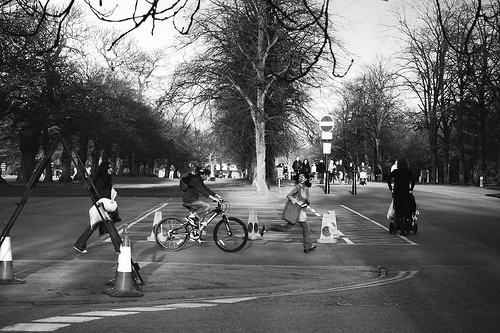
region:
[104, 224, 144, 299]
orange and white safety cone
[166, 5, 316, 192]
tree with no leaves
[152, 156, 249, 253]
boy riding a bicycle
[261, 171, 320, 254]
girl running across street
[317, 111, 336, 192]
round sign with white line through it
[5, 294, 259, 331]
white stripes painted on road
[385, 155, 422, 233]
woman pushing a baby carriage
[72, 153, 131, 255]
girl walking across street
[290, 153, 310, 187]
couple walking arm in arm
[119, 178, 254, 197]
shadow cast by tree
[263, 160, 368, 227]
Person runing acros the road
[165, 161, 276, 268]
man on a bicyvcle crossing the road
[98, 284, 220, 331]
road has white strip across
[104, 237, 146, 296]
black and white cones on th e road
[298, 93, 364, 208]
street light on th street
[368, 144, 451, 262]
man running through the highway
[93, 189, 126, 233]
lady carying a white sack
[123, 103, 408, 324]
the background color is black and white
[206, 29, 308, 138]
the tees in the middle of the road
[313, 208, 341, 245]
white cones on the road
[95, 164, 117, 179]
Person has long hair.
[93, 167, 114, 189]
Person has dark hair.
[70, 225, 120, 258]
Person wearing dark pants.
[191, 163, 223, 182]
Helmet on person's head.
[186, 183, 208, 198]
Person wearing dark shirt.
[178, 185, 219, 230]
Person riding on bike.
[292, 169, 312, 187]
Person has dark hair.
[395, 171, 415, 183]
Person wearing dark shirt.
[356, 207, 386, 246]
White lines marking road.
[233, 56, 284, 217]
Large tree in distance.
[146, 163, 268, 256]
man sitting on a bike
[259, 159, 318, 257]
person running in the street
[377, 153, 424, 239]
person riding on a bike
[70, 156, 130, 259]
person walking in the street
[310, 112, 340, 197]
street sign on a pole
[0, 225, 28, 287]
large safety cone in the street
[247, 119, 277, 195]
trunk of a large tree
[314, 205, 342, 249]
two saftey cones in the street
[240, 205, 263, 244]
small safety cone in the street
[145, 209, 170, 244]
small safety cone in the street